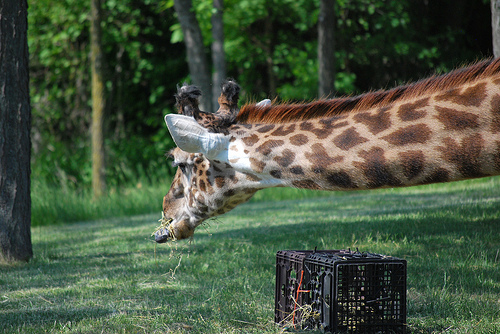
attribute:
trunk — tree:
[3, 2, 33, 270]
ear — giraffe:
[158, 77, 218, 135]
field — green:
[0, 138, 497, 331]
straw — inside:
[278, 304, 320, 327]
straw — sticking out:
[273, 292, 325, 332]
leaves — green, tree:
[167, 2, 267, 64]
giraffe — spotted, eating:
[148, 56, 491, 243]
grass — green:
[41, 250, 273, 330]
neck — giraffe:
[261, 54, 497, 190]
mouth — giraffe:
[158, 214, 176, 234]